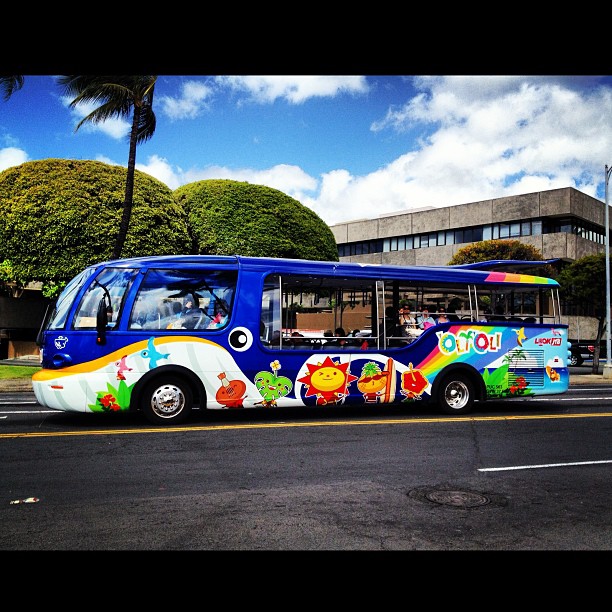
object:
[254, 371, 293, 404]
heart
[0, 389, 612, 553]
road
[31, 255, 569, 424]
bus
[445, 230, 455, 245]
window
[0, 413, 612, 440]
yellowline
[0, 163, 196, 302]
tree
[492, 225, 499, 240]
window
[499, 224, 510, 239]
window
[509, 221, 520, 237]
window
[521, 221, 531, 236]
window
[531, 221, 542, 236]
window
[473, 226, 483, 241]
window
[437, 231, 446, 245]
window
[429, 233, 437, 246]
window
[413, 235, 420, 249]
window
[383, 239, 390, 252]
window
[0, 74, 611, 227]
clouds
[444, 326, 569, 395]
scene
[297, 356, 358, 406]
decal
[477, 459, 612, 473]
line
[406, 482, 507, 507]
patch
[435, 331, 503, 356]
words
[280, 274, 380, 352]
windows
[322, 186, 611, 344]
building